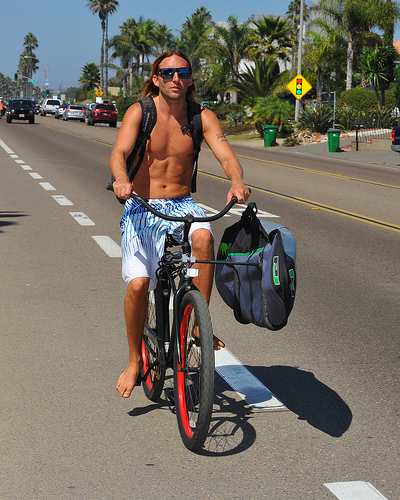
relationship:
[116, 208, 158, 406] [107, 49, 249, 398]
leg of guy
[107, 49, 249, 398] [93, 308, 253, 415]
guy has feet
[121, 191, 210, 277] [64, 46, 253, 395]
shorts on person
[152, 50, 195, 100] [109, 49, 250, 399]
head of guy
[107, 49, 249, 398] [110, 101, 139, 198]
guy has arm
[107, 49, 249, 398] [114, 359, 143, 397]
guy has foot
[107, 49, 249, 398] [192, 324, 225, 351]
guy has foot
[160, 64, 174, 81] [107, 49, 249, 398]
eye of a guy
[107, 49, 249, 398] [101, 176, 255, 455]
guy riding bike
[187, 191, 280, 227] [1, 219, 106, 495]
lettering on street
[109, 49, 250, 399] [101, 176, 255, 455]
guy on bike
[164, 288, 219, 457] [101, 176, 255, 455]
tire of bike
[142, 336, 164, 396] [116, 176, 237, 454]
rear tire on bike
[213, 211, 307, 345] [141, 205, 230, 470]
bag on bike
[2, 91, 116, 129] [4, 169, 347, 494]
vehicles on lane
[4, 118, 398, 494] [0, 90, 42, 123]
lane for traffic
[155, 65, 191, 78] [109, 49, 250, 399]
sunglasses of guy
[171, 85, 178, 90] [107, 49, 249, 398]
mouth of guy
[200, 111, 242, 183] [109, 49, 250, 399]
arm of guy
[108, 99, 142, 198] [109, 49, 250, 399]
arm of guy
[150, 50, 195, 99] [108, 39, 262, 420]
head on person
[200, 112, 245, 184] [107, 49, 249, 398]
arm on guy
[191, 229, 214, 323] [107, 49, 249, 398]
leg on guy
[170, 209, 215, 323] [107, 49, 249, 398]
leg on guy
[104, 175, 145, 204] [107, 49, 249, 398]
hand on guy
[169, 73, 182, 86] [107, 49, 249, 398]
nose on guy